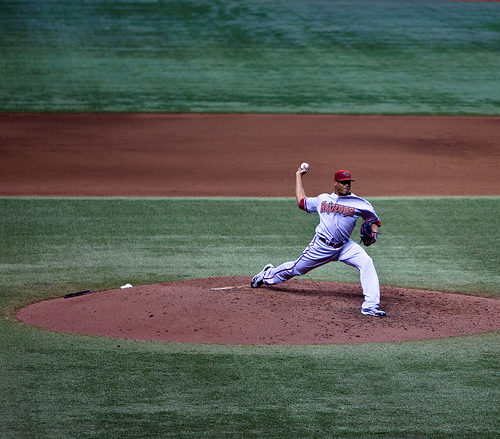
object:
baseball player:
[249, 163, 384, 319]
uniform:
[264, 193, 383, 307]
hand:
[296, 161, 307, 171]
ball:
[300, 162, 310, 168]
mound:
[17, 275, 499, 343]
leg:
[265, 239, 335, 286]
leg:
[341, 233, 384, 306]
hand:
[359, 221, 379, 246]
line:
[210, 280, 251, 291]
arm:
[292, 168, 317, 211]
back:
[311, 188, 371, 205]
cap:
[333, 168, 355, 183]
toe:
[250, 280, 261, 290]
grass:
[2, 2, 499, 436]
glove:
[358, 223, 376, 246]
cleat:
[251, 264, 271, 287]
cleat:
[362, 306, 384, 318]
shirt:
[304, 192, 380, 245]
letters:
[320, 199, 355, 218]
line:
[1, 190, 500, 202]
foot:
[358, 303, 388, 320]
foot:
[248, 261, 276, 287]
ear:
[333, 180, 339, 188]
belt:
[319, 235, 350, 249]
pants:
[262, 236, 382, 304]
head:
[334, 170, 354, 193]